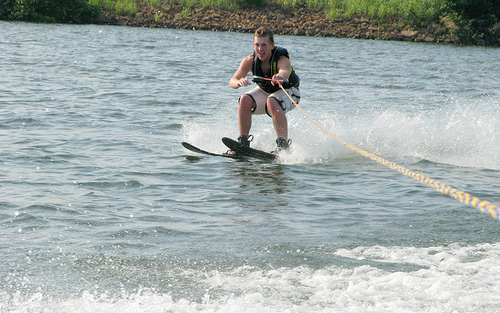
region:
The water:
[232, 181, 308, 284]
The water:
[262, 253, 317, 304]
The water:
[293, 258, 328, 307]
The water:
[254, 212, 310, 297]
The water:
[293, 287, 304, 304]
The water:
[285, 240, 337, 308]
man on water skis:
[166, 16, 483, 256]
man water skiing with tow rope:
[158, 21, 478, 241]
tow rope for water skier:
[259, 70, 474, 217]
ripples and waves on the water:
[38, 89, 105, 220]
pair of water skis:
[178, 127, 283, 182]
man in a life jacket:
[196, 17, 326, 117]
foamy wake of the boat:
[201, 249, 456, 303]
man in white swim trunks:
[225, 19, 340, 146]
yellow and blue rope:
[346, 142, 478, 215]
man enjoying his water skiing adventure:
[142, 15, 469, 260]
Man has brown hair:
[235, 22, 296, 47]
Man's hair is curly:
[246, 16, 282, 51]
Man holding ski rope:
[233, 67, 318, 106]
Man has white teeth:
[251, 45, 281, 61]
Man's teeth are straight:
[246, 48, 277, 60]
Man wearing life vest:
[239, 47, 324, 94]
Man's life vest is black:
[229, 41, 311, 92]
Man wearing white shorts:
[221, 77, 322, 134]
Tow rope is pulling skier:
[264, 70, 495, 213]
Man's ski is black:
[205, 131, 308, 181]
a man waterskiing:
[182, 2, 387, 202]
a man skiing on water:
[176, 15, 343, 205]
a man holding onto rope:
[202, 10, 449, 256]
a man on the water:
[146, 11, 399, 241]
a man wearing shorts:
[192, 0, 360, 192]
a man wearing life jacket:
[191, 21, 380, 225]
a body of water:
[10, 75, 127, 247]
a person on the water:
[190, 23, 369, 203]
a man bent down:
[179, 9, 421, 184]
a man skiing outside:
[200, 0, 382, 207]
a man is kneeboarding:
[131, 25, 399, 279]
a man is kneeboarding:
[164, 12, 321, 200]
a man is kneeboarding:
[204, 35, 344, 252]